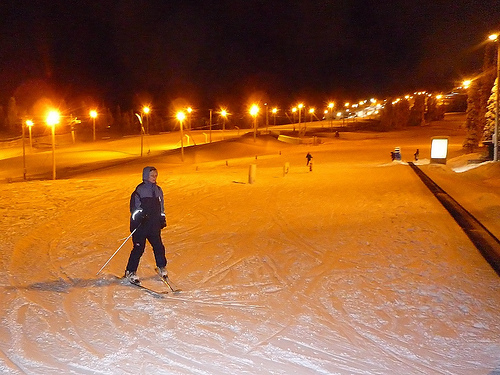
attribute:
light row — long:
[14, 89, 430, 183]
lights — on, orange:
[24, 91, 447, 180]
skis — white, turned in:
[108, 264, 183, 299]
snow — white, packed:
[2, 182, 498, 373]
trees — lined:
[379, 78, 500, 163]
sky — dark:
[2, 1, 499, 126]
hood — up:
[142, 165, 156, 182]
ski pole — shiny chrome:
[96, 223, 146, 284]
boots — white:
[125, 266, 169, 285]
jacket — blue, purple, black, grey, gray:
[130, 166, 165, 234]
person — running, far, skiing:
[305, 150, 313, 165]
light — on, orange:
[40, 110, 62, 180]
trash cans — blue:
[391, 146, 402, 162]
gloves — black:
[140, 216, 167, 229]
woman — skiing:
[126, 164, 169, 290]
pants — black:
[130, 232, 168, 271]